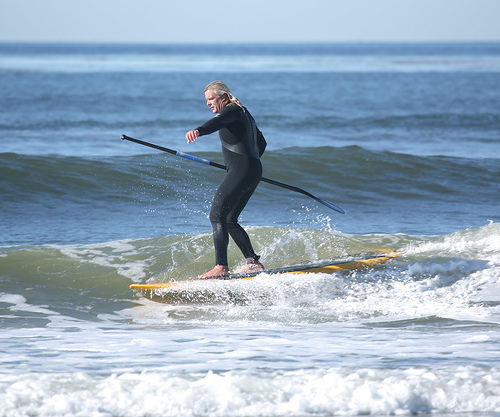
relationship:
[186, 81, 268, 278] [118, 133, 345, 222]
man has paddle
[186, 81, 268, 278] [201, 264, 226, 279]
man has foot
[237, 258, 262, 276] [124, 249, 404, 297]
foot standing on surfboard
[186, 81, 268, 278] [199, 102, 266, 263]
man wearing wetsuit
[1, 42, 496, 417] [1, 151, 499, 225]
ocean has wave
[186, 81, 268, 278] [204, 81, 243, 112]
man has hair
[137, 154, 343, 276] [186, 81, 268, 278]
water splashing around man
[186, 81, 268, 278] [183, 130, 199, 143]
man has hand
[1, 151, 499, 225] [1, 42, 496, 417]
wave forming in ocean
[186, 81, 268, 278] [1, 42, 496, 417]
man surfing in ocean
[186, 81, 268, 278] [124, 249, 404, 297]
man riding on surfboard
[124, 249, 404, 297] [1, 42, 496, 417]
surfboard on ocean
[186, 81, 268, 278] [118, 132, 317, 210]
man holding pole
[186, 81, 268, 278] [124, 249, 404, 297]
man surfing on surfboard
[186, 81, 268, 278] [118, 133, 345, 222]
man holding paddle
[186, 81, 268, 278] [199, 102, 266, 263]
man in wetsuit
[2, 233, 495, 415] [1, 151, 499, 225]
foamy area from wave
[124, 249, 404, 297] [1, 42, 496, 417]
surfboard on top of ocean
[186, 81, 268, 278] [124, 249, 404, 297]
man on surfboard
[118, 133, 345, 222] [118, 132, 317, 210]
paddle has pole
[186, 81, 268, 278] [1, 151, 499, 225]
man riding wave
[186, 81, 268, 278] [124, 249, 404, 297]
man riding surfboard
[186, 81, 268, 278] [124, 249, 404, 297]
man balancing on surfboard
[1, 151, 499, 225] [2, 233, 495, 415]
wave has foamy area